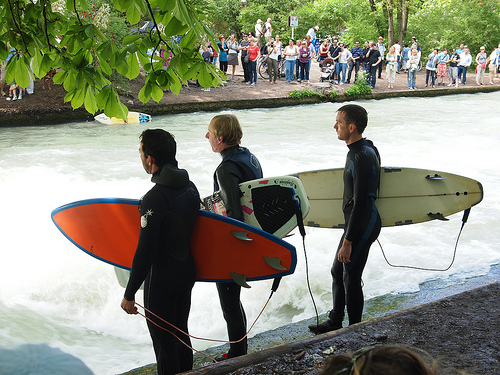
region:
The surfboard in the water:
[92, 109, 154, 126]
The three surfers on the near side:
[119, 101, 386, 373]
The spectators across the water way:
[92, 14, 498, 89]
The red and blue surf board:
[49, 192, 300, 299]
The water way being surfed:
[0, 89, 499, 373]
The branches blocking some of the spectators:
[0, 0, 232, 120]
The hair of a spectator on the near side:
[312, 336, 449, 373]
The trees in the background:
[194, 1, 498, 63]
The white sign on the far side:
[288, 7, 303, 40]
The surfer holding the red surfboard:
[119, 129, 201, 369]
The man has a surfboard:
[76, 170, 216, 315]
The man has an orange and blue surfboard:
[63, 188, 182, 279]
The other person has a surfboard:
[196, 171, 313, 241]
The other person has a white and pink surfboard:
[200, 122, 305, 248]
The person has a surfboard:
[288, 141, 443, 247]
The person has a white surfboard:
[301, 172, 468, 237]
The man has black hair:
[132, 112, 174, 172]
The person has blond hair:
[207, 102, 239, 152]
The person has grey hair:
[316, 105, 371, 150]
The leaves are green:
[25, 57, 126, 124]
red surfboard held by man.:
[80, 216, 126, 243]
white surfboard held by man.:
[405, 176, 427, 206]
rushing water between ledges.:
[406, 109, 473, 148]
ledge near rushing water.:
[178, 95, 270, 111]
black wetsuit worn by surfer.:
[343, 163, 365, 214]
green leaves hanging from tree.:
[51, 32, 128, 85]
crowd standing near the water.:
[282, 44, 384, 65]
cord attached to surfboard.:
[153, 312, 245, 347]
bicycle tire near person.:
[260, 55, 272, 80]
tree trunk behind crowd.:
[382, 8, 407, 35]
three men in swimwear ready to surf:
[35, 66, 418, 332]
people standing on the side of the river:
[156, 1, 456, 68]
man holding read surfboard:
[51, 185, 296, 280]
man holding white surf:
[307, 85, 393, 320]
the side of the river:
[119, 285, 497, 371]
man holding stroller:
[313, 33, 339, 86]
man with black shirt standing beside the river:
[363, 37, 382, 77]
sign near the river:
[282, 9, 305, 43]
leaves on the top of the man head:
[1, 5, 208, 111]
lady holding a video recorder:
[253, 28, 295, 93]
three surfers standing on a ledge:
[60, 87, 485, 368]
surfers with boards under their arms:
[46, 110, 481, 292]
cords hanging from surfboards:
[115, 205, 475, 342]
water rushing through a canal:
[70, 76, 440, 351]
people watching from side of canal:
[200, 25, 495, 95]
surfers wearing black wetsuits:
[97, 101, 387, 371]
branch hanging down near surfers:
[10, 10, 245, 175]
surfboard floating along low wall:
[60, 95, 155, 130]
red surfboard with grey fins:
[52, 195, 297, 295]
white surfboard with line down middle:
[297, 152, 483, 232]